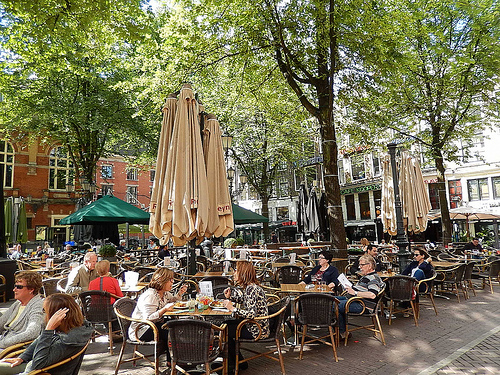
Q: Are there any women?
A: Yes, there are women.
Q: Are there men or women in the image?
A: Yes, there are women.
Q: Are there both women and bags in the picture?
A: No, there are women but no bags.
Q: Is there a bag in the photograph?
A: No, there are no bags.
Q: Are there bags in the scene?
A: No, there are no bags.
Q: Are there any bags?
A: No, there are no bags.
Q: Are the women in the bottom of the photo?
A: Yes, the women are in the bottom of the image.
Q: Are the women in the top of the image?
A: No, the women are in the bottom of the image.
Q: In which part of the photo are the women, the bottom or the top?
A: The women are in the bottom of the image.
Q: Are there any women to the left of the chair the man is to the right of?
A: Yes, there are women to the left of the chair.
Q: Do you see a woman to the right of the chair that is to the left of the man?
A: No, the women are to the left of the chair.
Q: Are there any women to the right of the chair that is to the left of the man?
A: No, the women are to the left of the chair.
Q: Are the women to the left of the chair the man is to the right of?
A: Yes, the women are to the left of the chair.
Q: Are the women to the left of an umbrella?
A: No, the women are to the left of the chair.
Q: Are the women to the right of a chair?
A: No, the women are to the left of a chair.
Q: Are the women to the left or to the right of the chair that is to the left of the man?
A: The women are to the left of the chair.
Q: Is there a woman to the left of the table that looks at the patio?
A: Yes, there are women to the left of the table.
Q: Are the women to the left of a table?
A: Yes, the women are to the left of a table.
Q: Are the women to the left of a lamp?
A: No, the women are to the left of a table.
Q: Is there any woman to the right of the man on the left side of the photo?
A: Yes, there are women to the right of the man.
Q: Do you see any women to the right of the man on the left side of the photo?
A: Yes, there are women to the right of the man.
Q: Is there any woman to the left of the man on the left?
A: No, the women are to the right of the man.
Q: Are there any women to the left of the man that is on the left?
A: No, the women are to the right of the man.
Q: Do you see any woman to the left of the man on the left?
A: No, the women are to the right of the man.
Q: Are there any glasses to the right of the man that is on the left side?
A: No, there are women to the right of the man.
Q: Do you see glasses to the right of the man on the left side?
A: No, there are women to the right of the man.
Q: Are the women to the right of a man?
A: Yes, the women are to the right of a man.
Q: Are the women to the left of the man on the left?
A: No, the women are to the right of the man.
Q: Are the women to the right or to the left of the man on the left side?
A: The women are to the right of the man.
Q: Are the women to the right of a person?
A: Yes, the women are to the right of a person.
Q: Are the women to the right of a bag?
A: No, the women are to the right of a person.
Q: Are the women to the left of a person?
A: No, the women are to the right of a person.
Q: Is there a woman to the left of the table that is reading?
A: Yes, there are women to the left of the table.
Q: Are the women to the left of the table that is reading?
A: Yes, the women are to the left of the table.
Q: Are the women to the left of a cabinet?
A: No, the women are to the left of the table.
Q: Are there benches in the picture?
A: No, there are no benches.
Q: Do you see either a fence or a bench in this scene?
A: No, there are no benches or fences.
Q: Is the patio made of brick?
A: Yes, the patio is made of brick.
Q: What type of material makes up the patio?
A: The patio is made of brick.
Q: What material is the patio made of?
A: The patio is made of brick.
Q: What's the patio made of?
A: The patio is made of brick.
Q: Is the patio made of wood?
A: No, the patio is made of brick.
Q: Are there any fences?
A: No, there are no fences.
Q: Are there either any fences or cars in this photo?
A: No, there are no fences or cars.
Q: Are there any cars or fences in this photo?
A: No, there are no fences or cars.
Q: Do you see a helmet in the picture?
A: No, there are no helmets.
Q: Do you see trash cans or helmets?
A: No, there are no helmets or trash cans.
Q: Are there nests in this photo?
A: No, there are no nests.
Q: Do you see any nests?
A: No, there are no nests.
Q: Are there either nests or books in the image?
A: No, there are no nests or books.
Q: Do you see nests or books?
A: No, there are no nests or books.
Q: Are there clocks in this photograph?
A: No, there are no clocks.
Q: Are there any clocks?
A: No, there are no clocks.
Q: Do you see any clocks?
A: No, there are no clocks.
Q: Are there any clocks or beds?
A: No, there are no clocks or beds.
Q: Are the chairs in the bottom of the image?
A: Yes, the chairs are in the bottom of the image.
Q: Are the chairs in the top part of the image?
A: No, the chairs are in the bottom of the image.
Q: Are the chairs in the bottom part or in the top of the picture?
A: The chairs are in the bottom of the image.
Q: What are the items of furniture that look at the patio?
A: The pieces of furniture are chairs.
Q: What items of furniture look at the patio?
A: The pieces of furniture are chairs.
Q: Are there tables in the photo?
A: Yes, there is a table.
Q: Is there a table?
A: Yes, there is a table.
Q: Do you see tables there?
A: Yes, there is a table.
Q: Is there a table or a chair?
A: Yes, there is a table.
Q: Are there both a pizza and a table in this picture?
A: No, there is a table but no pizzas.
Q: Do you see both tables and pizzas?
A: No, there is a table but no pizzas.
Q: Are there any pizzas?
A: No, there are no pizzas.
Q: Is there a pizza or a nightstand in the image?
A: No, there are no pizzas or nightstands.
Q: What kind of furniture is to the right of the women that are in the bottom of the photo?
A: The piece of furniture is a table.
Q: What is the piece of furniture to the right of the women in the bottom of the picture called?
A: The piece of furniture is a table.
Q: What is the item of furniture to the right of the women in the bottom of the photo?
A: The piece of furniture is a table.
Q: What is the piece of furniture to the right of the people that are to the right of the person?
A: The piece of furniture is a table.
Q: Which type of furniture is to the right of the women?
A: The piece of furniture is a table.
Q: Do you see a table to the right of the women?
A: Yes, there is a table to the right of the women.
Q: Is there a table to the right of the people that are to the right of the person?
A: Yes, there is a table to the right of the women.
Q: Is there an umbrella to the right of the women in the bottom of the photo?
A: No, there is a table to the right of the women.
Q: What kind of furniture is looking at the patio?
A: The piece of furniture is a table.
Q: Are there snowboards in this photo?
A: No, there are no snowboards.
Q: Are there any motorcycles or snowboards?
A: No, there are no snowboards or motorcycles.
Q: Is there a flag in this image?
A: No, there are no flags.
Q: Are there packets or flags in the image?
A: No, there are no flags or packets.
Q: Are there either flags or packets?
A: No, there are no flags or packets.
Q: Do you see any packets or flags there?
A: No, there are no flags or packets.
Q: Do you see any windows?
A: Yes, there is a window.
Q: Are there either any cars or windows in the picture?
A: Yes, there is a window.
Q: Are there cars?
A: No, there are no cars.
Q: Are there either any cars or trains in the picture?
A: No, there are no cars or trains.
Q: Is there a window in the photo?
A: Yes, there is a window.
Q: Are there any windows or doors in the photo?
A: Yes, there is a window.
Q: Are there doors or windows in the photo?
A: Yes, there is a window.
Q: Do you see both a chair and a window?
A: Yes, there are both a window and a chair.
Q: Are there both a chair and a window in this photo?
A: Yes, there are both a window and a chair.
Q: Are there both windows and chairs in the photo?
A: Yes, there are both a window and a chair.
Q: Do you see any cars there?
A: No, there are no cars.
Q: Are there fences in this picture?
A: No, there are no fences.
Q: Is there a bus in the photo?
A: No, there are no buses.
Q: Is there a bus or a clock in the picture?
A: No, there are no buses or clocks.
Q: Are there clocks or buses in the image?
A: No, there are no buses or clocks.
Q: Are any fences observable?
A: No, there are no fences.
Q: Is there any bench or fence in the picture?
A: No, there are no fences or benches.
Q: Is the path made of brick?
A: Yes, the path is made of brick.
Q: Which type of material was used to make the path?
A: The path is made of brick.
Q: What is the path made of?
A: The path is made of brick.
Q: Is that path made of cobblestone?
A: No, the path is made of brick.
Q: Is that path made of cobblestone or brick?
A: The path is made of brick.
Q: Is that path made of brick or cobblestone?
A: The path is made of brick.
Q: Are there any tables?
A: Yes, there is a table.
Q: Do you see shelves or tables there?
A: Yes, there is a table.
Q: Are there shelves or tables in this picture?
A: Yes, there is a table.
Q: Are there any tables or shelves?
A: Yes, there is a table.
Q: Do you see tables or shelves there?
A: Yes, there is a table.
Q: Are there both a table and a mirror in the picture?
A: No, there is a table but no mirrors.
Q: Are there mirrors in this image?
A: No, there are no mirrors.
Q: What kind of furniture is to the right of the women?
A: The piece of furniture is a table.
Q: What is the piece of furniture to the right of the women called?
A: The piece of furniture is a table.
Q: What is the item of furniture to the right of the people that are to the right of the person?
A: The piece of furniture is a table.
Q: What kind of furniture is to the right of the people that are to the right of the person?
A: The piece of furniture is a table.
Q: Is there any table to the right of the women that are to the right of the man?
A: Yes, there is a table to the right of the women.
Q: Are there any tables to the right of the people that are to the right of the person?
A: Yes, there is a table to the right of the women.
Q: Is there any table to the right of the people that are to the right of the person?
A: Yes, there is a table to the right of the women.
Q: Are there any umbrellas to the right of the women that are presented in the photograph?
A: No, there is a table to the right of the women.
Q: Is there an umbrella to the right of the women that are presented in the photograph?
A: No, there is a table to the right of the women.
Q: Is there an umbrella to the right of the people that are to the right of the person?
A: No, there is a table to the right of the women.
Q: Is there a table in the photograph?
A: Yes, there is a table.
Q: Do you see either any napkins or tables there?
A: Yes, there is a table.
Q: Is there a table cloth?
A: No, there are no tablecloths.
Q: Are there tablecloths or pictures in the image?
A: No, there are no tablecloths or pictures.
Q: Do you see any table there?
A: Yes, there is a table.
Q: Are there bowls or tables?
A: Yes, there is a table.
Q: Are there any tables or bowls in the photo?
A: Yes, there is a table.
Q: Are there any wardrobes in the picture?
A: No, there are no wardrobes.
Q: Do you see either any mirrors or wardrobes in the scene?
A: No, there are no wardrobes or mirrors.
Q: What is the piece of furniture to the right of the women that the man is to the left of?
A: The piece of furniture is a table.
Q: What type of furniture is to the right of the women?
A: The piece of furniture is a table.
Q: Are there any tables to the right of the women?
A: Yes, there is a table to the right of the women.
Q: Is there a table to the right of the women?
A: Yes, there is a table to the right of the women.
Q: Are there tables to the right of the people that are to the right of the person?
A: Yes, there is a table to the right of the women.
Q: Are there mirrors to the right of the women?
A: No, there is a table to the right of the women.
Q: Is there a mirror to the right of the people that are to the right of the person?
A: No, there is a table to the right of the women.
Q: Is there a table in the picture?
A: Yes, there is a table.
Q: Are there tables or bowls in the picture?
A: Yes, there is a table.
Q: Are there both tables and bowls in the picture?
A: No, there is a table but no bowls.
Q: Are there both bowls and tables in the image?
A: No, there is a table but no bowls.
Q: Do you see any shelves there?
A: No, there are no shelves.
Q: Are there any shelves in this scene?
A: No, there are no shelves.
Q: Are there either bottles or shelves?
A: No, there are no shelves or bottles.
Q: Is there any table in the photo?
A: Yes, there is a table.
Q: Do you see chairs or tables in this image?
A: Yes, there is a table.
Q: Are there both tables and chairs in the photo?
A: Yes, there are both a table and a chair.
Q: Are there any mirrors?
A: No, there are no mirrors.